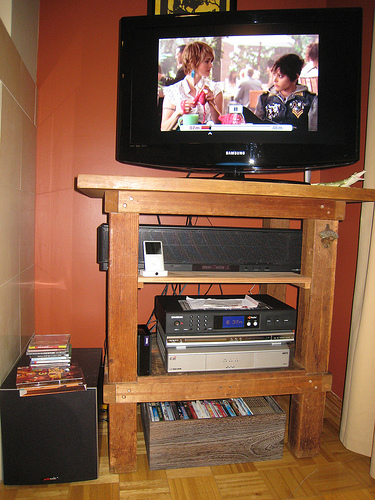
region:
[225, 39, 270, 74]
part of a screen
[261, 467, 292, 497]
part of a floor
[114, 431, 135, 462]
part of a stand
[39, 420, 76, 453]
part of a speaker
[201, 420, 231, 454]
part of a box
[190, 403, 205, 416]
part of some books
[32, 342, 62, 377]
pile of some books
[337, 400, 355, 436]
part of a curtain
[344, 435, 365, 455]
edge of a curtain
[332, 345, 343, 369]
part of a wall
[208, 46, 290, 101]
part of a screen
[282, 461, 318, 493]
part of a floor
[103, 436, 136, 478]
part of a stand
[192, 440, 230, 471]
part of a box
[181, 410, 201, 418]
part of some books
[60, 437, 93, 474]
part of a speaker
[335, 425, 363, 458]
edge of a curtain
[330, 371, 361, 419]
part of a curtain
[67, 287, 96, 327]
part of a wall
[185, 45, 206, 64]
hair of a lady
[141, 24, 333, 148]
Movie scene on television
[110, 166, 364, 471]
Brown wooden entertainment center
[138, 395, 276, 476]
DVD movies in a brown box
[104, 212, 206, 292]
Apple ipod on shelf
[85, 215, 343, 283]
Bluetooth speaker on shelf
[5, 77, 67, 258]
Light brown tiled wall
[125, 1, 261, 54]
Yellow picture on background wall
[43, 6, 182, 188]
Orange wall behind television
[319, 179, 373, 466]
Light brown curtain next to shelf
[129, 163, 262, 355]
Electronics wires behind shelf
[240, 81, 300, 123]
screen of a television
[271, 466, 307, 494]
part of a floor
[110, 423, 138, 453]
part of a stand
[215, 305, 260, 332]
part of a video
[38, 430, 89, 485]
part of a speaker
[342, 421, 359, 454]
part of a curtain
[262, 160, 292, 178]
edge of a television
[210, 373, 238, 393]
part of a wood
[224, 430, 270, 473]
part of a box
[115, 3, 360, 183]
color television on stand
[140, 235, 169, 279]
cell phone in charger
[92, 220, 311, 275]
large speaker on shelf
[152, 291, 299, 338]
cable box for tv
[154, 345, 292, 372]
dvd/cd player under cable box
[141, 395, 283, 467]
box of cd's for cd player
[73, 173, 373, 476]
wooden table with two shelves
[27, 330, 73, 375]
stack of cd boxes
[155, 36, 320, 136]
scene from tv program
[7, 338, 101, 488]
large black speaker on floor